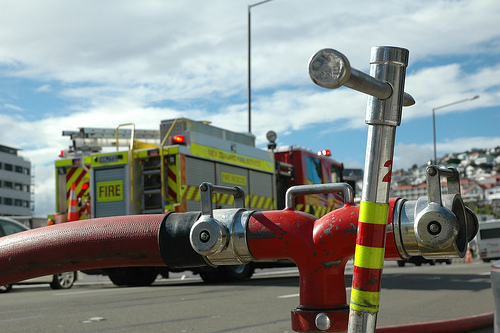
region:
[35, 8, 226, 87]
The clouds are in the sky.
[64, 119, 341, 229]
The fire truck is moving.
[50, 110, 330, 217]
The fire truck is yellow and red.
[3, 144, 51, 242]
The building is white.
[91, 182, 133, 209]
The sign is yellow.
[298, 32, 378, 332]
The pole is metal.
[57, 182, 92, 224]
The cone is orange.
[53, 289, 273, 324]
The street is grey and clear.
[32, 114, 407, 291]
The fire truck is driving on the street.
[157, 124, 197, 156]
The red light is on.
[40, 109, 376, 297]
red, gray, and yellow fire truck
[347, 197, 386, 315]
red and yellow stripes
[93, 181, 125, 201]
red lettering on a yellow background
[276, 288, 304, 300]
white line painted on the ground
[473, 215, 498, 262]
back of a white bus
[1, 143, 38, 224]
concrete parking garage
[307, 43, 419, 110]
long silver screw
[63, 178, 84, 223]
orange and white traffic cone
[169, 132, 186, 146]
bright orange light on the back of the truck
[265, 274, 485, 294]
shadow on the road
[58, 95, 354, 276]
fire truck on the road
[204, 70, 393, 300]
fire hose connected to watter supply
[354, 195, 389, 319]
yellow and red tape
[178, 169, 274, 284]
metal hose connector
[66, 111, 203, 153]
ladder is on top of truck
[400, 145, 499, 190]
hillside covered with houses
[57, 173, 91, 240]
traffic cone on back of truck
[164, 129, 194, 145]
light on back of truck is on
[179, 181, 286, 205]
yellow and red stripes on truck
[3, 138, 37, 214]
multi-story building beside road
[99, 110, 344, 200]
the fire track is yellow and red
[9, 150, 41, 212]
the building is white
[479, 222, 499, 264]
the van is white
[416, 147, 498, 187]
the houses are on the hill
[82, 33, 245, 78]
cloudsa are in the sky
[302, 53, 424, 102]
the nail is silver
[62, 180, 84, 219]
the cone is yellow and white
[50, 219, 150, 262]
the pipe is red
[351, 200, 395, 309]
the strips are red and yellow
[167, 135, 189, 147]
the light is on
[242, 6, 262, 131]
grey metal light pole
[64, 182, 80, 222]
orange and white safety cone on fire truck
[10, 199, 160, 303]
red fire hose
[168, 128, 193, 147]
red light on back of fire truck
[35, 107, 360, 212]
red and yellow fire truck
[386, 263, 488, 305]
shadow of fire truck on road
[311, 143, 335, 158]
red emergency light on top of fire truck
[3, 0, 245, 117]
sky filled with clouds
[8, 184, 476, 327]
fire hose attached to hydrant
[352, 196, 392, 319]
red and yellow tape on metal pole